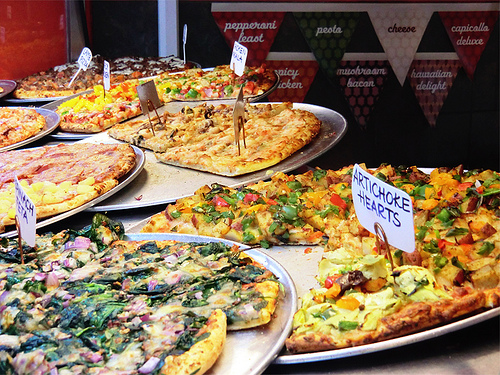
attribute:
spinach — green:
[66, 237, 271, 351]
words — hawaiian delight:
[409, 68, 454, 93]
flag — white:
[365, 9, 433, 85]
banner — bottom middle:
[327, 44, 397, 134]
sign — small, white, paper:
[74, 42, 93, 69]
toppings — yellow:
[4, 175, 89, 216]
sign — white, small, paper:
[202, 33, 269, 161]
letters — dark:
[352, 169, 411, 240]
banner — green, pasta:
[306, 20, 375, 78]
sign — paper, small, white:
[99, 61, 116, 96]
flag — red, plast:
[215, 7, 280, 68]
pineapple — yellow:
[59, 85, 110, 115]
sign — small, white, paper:
[350, 161, 416, 255]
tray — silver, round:
[68, 89, 349, 218]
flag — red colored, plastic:
[444, 11, 494, 76]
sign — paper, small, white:
[136, 77, 164, 107]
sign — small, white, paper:
[232, 100, 287, 149]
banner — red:
[332, 150, 431, 265]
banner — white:
[335, 6, 431, 71]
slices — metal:
[117, 98, 309, 177]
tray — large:
[59, 101, 346, 214]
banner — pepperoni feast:
[215, 15, 275, 65]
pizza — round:
[143, 169, 498, 346]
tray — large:
[126, 160, 498, 366]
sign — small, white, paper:
[346, 155, 418, 262]